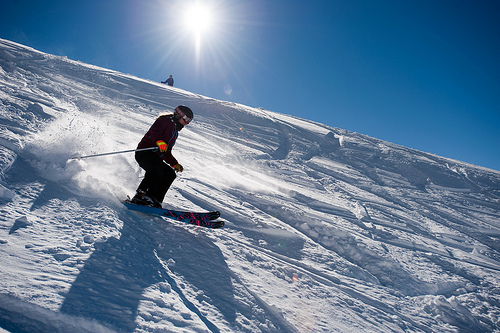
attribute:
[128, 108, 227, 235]
person — skiing., looking., skiing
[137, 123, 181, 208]
clothes — black., black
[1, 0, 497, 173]
sky — multicolored, blue., blue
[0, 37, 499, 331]
snow — white, flying, splashing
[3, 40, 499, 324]
hill — snowy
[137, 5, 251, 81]
sun — bright., shining, bright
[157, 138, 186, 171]
gloves — orange.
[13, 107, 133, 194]
cloud — splashing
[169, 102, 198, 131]
helmet — black., black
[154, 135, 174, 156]
glove — striped, orange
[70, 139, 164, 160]
pole — silver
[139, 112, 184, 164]
jacket — dark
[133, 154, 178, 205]
pants — black.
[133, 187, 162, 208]
boots — dark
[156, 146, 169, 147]
stripe — yellow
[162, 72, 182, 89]
skier — far